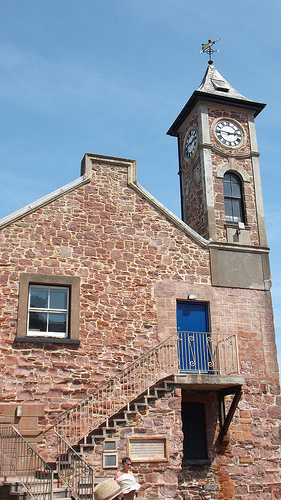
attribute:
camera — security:
[234, 220, 248, 239]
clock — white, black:
[207, 115, 253, 154]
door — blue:
[178, 300, 210, 371]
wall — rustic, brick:
[0, 162, 279, 498]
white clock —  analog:
[210, 114, 250, 150]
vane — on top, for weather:
[198, 35, 222, 63]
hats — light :
[92, 471, 140, 498]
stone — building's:
[73, 355, 89, 367]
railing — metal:
[1, 330, 241, 498]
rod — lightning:
[203, 43, 213, 63]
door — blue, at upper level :
[176, 299, 212, 372]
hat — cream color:
[92, 476, 131, 499]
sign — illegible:
[134, 438, 170, 458]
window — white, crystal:
[26, 283, 68, 336]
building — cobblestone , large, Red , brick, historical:
[4, 62, 276, 498]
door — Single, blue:
[173, 298, 219, 375]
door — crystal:
[174, 297, 210, 374]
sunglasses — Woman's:
[125, 461, 133, 467]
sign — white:
[122, 429, 169, 464]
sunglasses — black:
[124, 462, 132, 466]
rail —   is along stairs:
[76, 314, 245, 415]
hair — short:
[119, 456, 131, 464]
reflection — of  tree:
[26, 293, 48, 313]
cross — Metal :
[199, 39, 221, 63]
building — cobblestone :
[179, 101, 269, 239]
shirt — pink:
[115, 470, 132, 474]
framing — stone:
[69, 269, 87, 349]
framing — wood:
[114, 439, 120, 468]